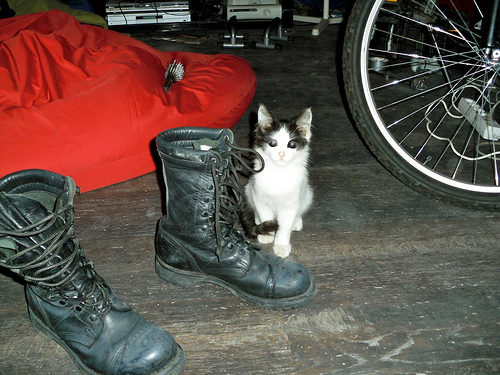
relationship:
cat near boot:
[238, 102, 314, 259] [1, 168, 184, 373]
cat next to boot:
[238, 102, 314, 259] [1, 168, 184, 373]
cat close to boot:
[238, 102, 314, 259] [1, 168, 184, 373]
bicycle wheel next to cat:
[341, 0, 499, 212] [238, 102, 314, 259]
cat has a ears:
[238, 102, 314, 259] [294, 107, 311, 127]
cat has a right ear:
[238, 102, 314, 259] [257, 104, 274, 131]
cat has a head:
[238, 102, 314, 259] [256, 104, 312, 166]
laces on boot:
[210, 136, 265, 261] [154, 128, 316, 310]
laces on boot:
[0, 186, 111, 321] [1, 169, 186, 374]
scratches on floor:
[1, 183, 500, 374] [1, 26, 498, 375]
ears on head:
[258, 102, 313, 133] [256, 104, 312, 166]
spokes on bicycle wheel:
[368, 0, 500, 187] [341, 0, 499, 212]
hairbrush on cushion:
[163, 58, 185, 91] [0, 8, 256, 196]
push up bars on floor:
[217, 16, 293, 48] [1, 26, 498, 375]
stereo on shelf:
[107, 10, 190, 27] [106, 19, 294, 30]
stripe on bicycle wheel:
[361, 0, 499, 195] [341, 0, 499, 212]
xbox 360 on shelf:
[216, 3, 283, 20] [106, 19, 294, 30]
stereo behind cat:
[107, 10, 190, 27] [238, 102, 314, 259]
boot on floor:
[154, 128, 316, 310] [1, 26, 498, 375]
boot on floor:
[1, 169, 186, 374] [1, 26, 498, 375]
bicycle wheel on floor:
[341, 0, 499, 212] [1, 26, 498, 375]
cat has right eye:
[238, 102, 314, 259] [268, 140, 278, 148]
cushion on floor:
[0, 8, 256, 196] [1, 26, 498, 375]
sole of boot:
[155, 258, 317, 310] [154, 128, 316, 310]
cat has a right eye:
[238, 102, 314, 259] [267, 139, 278, 147]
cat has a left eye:
[238, 102, 314, 259] [286, 141, 297, 149]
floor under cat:
[1, 26, 498, 375] [238, 102, 314, 259]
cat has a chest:
[238, 102, 314, 259] [254, 165, 306, 208]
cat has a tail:
[238, 102, 314, 259] [239, 186, 278, 237]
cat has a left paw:
[238, 102, 314, 259] [273, 243, 293, 258]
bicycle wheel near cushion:
[341, 0, 499, 212] [0, 8, 256, 196]